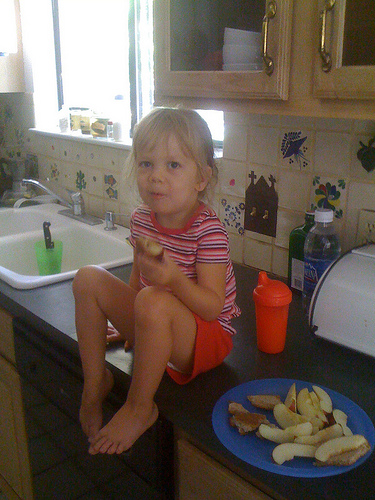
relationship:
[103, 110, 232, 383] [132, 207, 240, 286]
girl wearing shirt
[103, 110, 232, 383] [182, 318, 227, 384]
girl wearing shorts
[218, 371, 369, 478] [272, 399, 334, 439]
plate with apples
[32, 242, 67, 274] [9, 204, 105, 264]
cup in sink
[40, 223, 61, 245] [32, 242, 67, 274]
knife in cup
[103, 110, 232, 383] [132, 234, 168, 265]
girl eating food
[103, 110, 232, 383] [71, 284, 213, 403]
girl sitting on counter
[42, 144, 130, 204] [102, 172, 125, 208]
tile with fish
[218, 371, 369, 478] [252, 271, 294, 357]
plate near cup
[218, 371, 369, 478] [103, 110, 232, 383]
plate near girl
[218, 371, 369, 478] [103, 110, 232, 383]
plate close to girl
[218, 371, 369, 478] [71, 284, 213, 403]
plate on top of counter